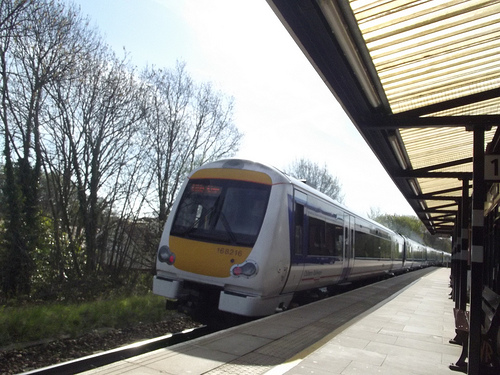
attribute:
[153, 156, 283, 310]
front is yellow — white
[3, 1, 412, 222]
sky is blue — grey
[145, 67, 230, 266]
tree is brown — barren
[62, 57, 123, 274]
tree is brown — barren, bare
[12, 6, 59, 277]
tree is brown — barren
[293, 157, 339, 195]
tree is brown — barren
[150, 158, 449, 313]
train is white — yellow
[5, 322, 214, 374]
track is metal — silver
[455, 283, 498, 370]
bench is brown — empty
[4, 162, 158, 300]
plants are green — greem